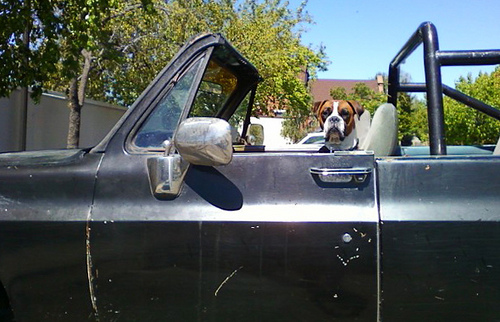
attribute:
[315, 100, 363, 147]
dog — large, copper-colored, brown, white, sitting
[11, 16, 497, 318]
car — black, old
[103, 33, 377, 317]
door — closed, painted black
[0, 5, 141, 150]
tree — green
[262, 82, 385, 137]
building — brown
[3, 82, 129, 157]
wall — white, concrete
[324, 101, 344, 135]
stripe — white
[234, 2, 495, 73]
sky — blue, clear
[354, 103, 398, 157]
seats — gray, open behind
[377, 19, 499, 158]
roll bars — black, metallic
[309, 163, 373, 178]
handle — silver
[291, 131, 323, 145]
another car — parked nearby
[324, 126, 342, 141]
jowls — droopy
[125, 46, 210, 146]
window — triangular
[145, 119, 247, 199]
mirror — metallic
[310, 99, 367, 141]
face — brown, black, white